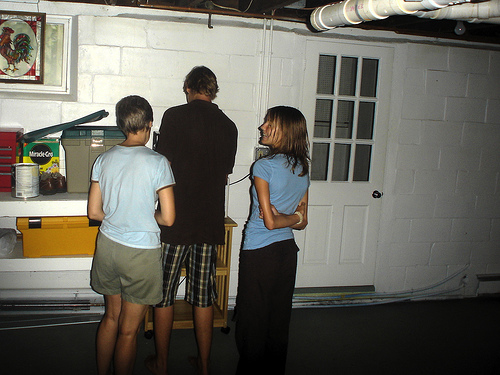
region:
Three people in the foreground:
[77, 62, 323, 372]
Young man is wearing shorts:
[148, 235, 226, 335]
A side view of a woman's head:
[246, 99, 323, 183]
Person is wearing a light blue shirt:
[81, 134, 185, 261]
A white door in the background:
[285, 36, 409, 295]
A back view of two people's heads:
[82, 46, 239, 373]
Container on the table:
[52, 111, 132, 199]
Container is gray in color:
[58, 120, 135, 204]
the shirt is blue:
[272, 165, 287, 185]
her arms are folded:
[272, 201, 299, 233]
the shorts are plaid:
[195, 263, 210, 287]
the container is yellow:
[38, 234, 74, 246]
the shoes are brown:
[41, 172, 61, 190]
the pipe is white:
[324, 9, 364, 22]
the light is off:
[447, 21, 472, 37]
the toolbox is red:
[5, 136, 13, 167]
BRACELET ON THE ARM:
[295, 207, 303, 227]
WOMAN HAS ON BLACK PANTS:
[265, 257, 286, 268]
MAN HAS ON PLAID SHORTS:
[196, 248, 204, 273]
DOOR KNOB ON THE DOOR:
[366, 184, 384, 200]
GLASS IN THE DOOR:
[331, 142, 348, 180]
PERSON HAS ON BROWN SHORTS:
[133, 262, 152, 283]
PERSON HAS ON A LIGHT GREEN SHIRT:
[123, 172, 135, 203]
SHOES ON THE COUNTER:
[44, 173, 69, 200]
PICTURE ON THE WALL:
[1, 12, 83, 93]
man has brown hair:
[180, 53, 212, 90]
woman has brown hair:
[252, 95, 324, 153]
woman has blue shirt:
[253, 151, 320, 256]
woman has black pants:
[201, 224, 306, 351]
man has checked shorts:
[169, 231, 216, 301]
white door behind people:
[295, 42, 386, 281]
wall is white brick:
[403, 81, 468, 224]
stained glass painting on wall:
[5, 25, 72, 88]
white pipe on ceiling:
[288, 3, 403, 35]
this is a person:
[234, 100, 321, 364]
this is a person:
[150, 32, 224, 372]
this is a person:
[54, 68, 183, 373]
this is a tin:
[9, 150, 46, 216]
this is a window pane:
[314, 138, 326, 178]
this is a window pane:
[327, 138, 355, 179]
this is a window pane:
[353, 136, 374, 183]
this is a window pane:
[314, 91, 332, 138]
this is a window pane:
[336, 96, 352, 136]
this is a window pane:
[357, 97, 372, 147]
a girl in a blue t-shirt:
[235, 103, 312, 373]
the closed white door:
[293, 40, 396, 289]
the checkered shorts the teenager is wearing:
[153, 240, 215, 307]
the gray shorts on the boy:
[90, 230, 165, 303]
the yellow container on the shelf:
[16, 215, 101, 255]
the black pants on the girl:
[234, 239, 297, 374]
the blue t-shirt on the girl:
[241, 149, 310, 251]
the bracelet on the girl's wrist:
[293, 209, 303, 226]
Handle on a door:
[367, 188, 384, 200]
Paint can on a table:
[3, 159, 45, 201]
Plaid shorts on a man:
[156, 241, 219, 309]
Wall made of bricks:
[406, 122, 496, 223]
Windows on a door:
[313, 97, 373, 185]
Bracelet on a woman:
[293, 209, 305, 224]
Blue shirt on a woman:
[241, 156, 307, 246]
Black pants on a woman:
[234, 229, 311, 372]